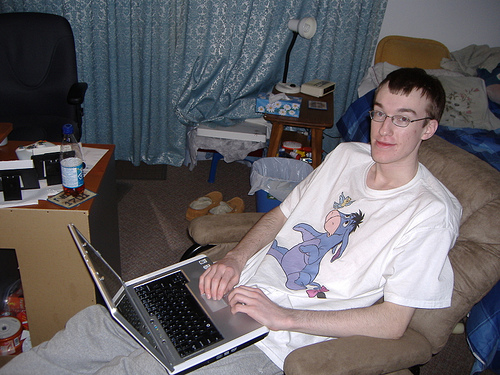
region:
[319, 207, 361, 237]
eeyore is on the shirt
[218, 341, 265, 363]
the laptop is on his lap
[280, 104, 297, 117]
the flowers are white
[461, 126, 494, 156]
the bed is made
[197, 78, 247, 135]
the curtain is on the stand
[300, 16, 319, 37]
the lamp is off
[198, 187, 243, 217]
the slippers are on the floor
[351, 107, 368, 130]
the banket is blue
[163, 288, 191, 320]
the keyboard is black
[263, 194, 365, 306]
cartoon character on a tee shirt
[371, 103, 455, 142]
man wearing reading glasses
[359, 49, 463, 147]
man with brown hair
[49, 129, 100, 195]
bottle on a table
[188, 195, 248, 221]
brown shoes on the floor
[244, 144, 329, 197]
trash can on the floor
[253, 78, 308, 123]
box of tissue on the table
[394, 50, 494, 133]
pillow on the bed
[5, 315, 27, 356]
case of cd's on the floor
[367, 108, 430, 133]
glasses on the man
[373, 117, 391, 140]
the young man's nose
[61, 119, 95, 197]
bottle of tea on desk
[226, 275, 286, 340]
the man's left hand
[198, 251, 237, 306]
the man's right hand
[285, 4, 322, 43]
white lamp on desk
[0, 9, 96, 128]
black computer chair at desk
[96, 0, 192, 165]
blue curtain on window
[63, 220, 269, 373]
silver laptop on man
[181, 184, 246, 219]
brown shoes on floor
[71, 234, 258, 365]
this is a lapotp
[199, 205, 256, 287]
this is a hand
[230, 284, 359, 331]
this is a hand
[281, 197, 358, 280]
a cartoon on the t shirt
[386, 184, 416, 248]
the t shirt is white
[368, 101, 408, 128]
the person is wearing spectacles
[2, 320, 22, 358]
this is a can of paint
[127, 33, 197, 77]
this is a curtain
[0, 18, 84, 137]
this is a chair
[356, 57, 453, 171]
man with blonde hair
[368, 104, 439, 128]
man wearing wired glasses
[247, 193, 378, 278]
cartoon character on a tee shirt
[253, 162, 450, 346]
man wearing a white tee shirt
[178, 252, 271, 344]
man using a laptop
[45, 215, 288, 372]
laptop resting on a mans legs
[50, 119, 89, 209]
bottle on the table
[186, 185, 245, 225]
shoes on the carpet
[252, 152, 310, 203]
trash bag in the garbage can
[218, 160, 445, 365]
man seating in a recliner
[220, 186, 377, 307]
drawing on the shirt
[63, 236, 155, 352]
screen of the computer